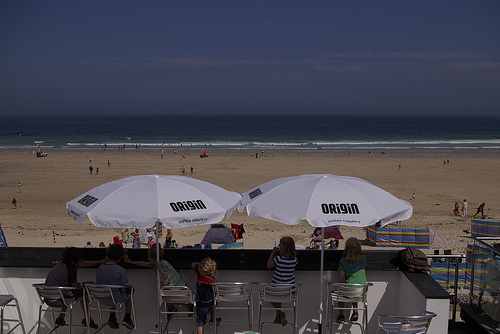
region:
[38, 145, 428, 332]
two white umbrellas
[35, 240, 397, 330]
kids sitting under umbrella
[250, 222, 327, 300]
girl wearing striped top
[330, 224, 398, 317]
girl wearing green shirt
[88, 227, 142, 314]
boy wearing blue shirt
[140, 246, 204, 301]
boy wearing green shirt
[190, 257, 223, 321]
boy wearing black and red shirt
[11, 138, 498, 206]
people on the beach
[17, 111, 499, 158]
the blue sea water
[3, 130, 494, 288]
sand on the beach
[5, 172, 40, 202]
Person standing in the sand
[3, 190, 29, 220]
Person standing in the sand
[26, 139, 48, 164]
Person standing in the sand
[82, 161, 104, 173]
Person standing in the sand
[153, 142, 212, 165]
Person standing in the sand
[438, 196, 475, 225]
Person standing in the sand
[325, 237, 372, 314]
Person sitting in chair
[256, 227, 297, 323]
Person sitting in chair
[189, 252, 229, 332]
Person sitting in chair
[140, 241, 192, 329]
Person sitting in chair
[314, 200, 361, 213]
logo on the umbrella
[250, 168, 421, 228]
umbrella is white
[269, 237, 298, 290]
a person sitting in a chair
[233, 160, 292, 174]
sand on the beach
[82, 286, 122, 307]
a silver chair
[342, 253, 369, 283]
person wearing a green shirt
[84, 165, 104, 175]
people on the beach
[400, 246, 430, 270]
a brown bag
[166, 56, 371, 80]
clouds in the sky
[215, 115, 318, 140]
the water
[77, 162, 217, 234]
white umbrella over sand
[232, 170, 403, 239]
white umbrella over sand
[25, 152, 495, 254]
large sandy beach in background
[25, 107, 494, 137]
large ocean in distance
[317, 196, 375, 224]
black logo on white umbrella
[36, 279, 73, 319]
small metal chair in foreground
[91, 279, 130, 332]
small metal chair in foreground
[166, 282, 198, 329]
small metal chair in foreground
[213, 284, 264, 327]
small metal chair in foreground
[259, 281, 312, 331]
small metal chair in foreground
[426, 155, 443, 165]
part of a beach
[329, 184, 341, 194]
part of an umbrella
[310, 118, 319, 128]
part of a ocean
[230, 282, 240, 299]
part of a chair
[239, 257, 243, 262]
part of a table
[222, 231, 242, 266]
edge of a table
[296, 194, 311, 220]
edge of an umbrella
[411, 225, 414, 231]
part of a water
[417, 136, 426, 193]
part of a floater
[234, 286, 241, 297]
back of a seat